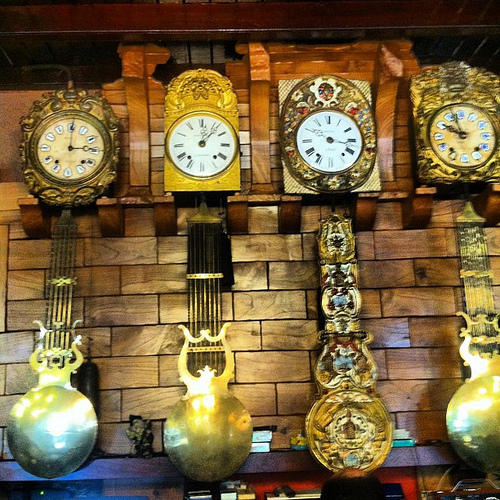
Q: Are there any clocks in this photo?
A: Yes, there is a clock.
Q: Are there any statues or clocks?
A: Yes, there is a clock.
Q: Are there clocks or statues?
A: Yes, there is a clock.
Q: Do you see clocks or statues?
A: Yes, there is a clock.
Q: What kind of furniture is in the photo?
A: The furniture is a shelf.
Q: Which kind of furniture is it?
A: The piece of furniture is a shelf.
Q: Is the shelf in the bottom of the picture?
A: Yes, the shelf is in the bottom of the image.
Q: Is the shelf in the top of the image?
A: No, the shelf is in the bottom of the image.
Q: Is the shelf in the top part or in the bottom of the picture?
A: The shelf is in the bottom of the image.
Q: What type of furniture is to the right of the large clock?
A: The piece of furniture is a shelf.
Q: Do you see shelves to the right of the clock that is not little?
A: Yes, there is a shelf to the right of the clock.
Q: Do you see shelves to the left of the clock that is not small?
A: No, the shelf is to the right of the clock.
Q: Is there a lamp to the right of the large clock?
A: No, there is a shelf to the right of the clock.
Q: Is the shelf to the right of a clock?
A: Yes, the shelf is to the right of a clock.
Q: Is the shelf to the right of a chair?
A: No, the shelf is to the right of a clock.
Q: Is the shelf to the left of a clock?
A: No, the shelf is to the right of a clock.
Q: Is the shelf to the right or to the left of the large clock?
A: The shelf is to the right of the clock.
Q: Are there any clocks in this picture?
A: Yes, there is a clock.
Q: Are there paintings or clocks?
A: Yes, there is a clock.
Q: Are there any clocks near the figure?
A: Yes, there is a clock near the figure.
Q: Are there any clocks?
A: Yes, there is a clock.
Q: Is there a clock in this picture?
A: Yes, there is a clock.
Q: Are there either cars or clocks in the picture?
A: Yes, there is a clock.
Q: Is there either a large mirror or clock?
A: Yes, there is a large clock.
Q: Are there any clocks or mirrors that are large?
A: Yes, the clock is large.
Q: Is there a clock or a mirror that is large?
A: Yes, the clock is large.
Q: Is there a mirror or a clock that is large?
A: Yes, the clock is large.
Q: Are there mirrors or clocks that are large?
A: Yes, the clock is large.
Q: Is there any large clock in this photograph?
A: Yes, there is a large clock.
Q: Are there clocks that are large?
A: Yes, there is a clock that is large.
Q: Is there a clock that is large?
A: Yes, there is a clock that is large.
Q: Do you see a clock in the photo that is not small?
A: Yes, there is a large clock.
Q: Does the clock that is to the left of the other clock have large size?
A: Yes, the clock is large.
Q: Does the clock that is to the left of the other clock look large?
A: Yes, the clock is large.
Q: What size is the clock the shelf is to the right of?
A: The clock is large.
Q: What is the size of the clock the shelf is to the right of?
A: The clock is large.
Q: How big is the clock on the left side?
A: The clock is large.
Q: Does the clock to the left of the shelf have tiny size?
A: No, the clock is large.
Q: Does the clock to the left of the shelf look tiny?
A: No, the clock is large.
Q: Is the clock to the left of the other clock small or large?
A: The clock is large.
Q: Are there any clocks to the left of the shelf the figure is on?
A: Yes, there is a clock to the left of the shelf.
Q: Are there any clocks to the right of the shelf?
A: No, the clock is to the left of the shelf.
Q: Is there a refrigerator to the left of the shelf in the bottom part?
A: No, there is a clock to the left of the shelf.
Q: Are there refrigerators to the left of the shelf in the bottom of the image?
A: No, there is a clock to the left of the shelf.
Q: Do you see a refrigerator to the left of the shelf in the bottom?
A: No, there is a clock to the left of the shelf.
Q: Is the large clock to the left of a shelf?
A: Yes, the clock is to the left of a shelf.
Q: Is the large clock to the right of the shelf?
A: No, the clock is to the left of the shelf.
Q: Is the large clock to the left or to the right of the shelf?
A: The clock is to the left of the shelf.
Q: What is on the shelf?
A: The figure is on the shelf.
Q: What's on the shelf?
A: The figure is on the shelf.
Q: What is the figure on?
A: The figure is on the shelf.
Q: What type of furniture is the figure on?
A: The figure is on the shelf.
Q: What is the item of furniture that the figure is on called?
A: The piece of furniture is a shelf.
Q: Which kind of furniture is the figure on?
A: The figure is on the shelf.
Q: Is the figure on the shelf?
A: Yes, the figure is on the shelf.